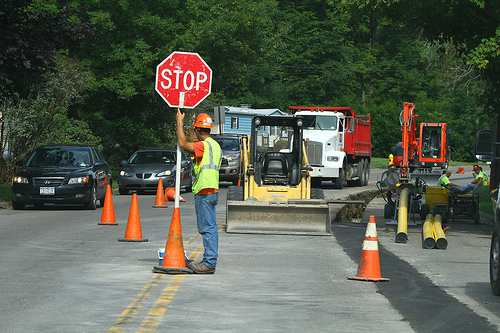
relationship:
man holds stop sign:
[173, 107, 222, 276] [152, 41, 219, 119]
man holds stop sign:
[173, 107, 222, 276] [148, 48, 218, 118]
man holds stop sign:
[173, 107, 222, 276] [150, 46, 219, 111]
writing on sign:
[146, 44, 220, 116] [150, 39, 217, 111]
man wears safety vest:
[173, 107, 222, 276] [189, 135, 225, 195]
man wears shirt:
[173, 107, 222, 276] [190, 139, 222, 193]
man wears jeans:
[173, 107, 222, 276] [190, 192, 226, 266]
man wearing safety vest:
[173, 107, 222, 276] [188, 134, 223, 194]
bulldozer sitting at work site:
[222, 113, 333, 237] [96, 159, 484, 293]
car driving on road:
[9, 141, 115, 208] [0, 162, 484, 330]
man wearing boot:
[173, 107, 222, 276] [186, 260, 216, 273]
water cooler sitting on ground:
[155, 247, 187, 268] [1, 165, 484, 331]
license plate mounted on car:
[37, 184, 57, 195] [9, 141, 115, 208]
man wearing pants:
[173, 107, 222, 276] [193, 191, 220, 270]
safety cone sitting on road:
[346, 213, 391, 283] [0, 165, 499, 332]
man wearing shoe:
[173, 107, 222, 276] [186, 261, 216, 274]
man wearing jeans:
[173, 107, 222, 276] [192, 190, 221, 273]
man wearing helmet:
[173, 107, 223, 274] [187, 110, 214, 129]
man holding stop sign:
[173, 107, 222, 276] [153, 47, 212, 207]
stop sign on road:
[153, 47, 212, 207] [0, 162, 484, 330]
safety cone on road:
[153, 203, 193, 275] [0, 162, 484, 330]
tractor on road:
[374, 99, 448, 185] [0, 162, 484, 330]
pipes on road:
[394, 185, 451, 251] [0, 162, 484, 330]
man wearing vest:
[173, 107, 222, 276] [190, 136, 223, 193]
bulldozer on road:
[222, 114, 333, 237] [0, 165, 499, 332]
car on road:
[9, 141, 115, 208] [0, 165, 499, 332]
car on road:
[116, 146, 193, 192] [0, 162, 484, 330]